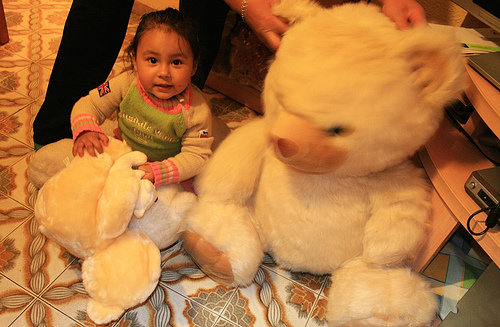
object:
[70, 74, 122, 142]
sleeve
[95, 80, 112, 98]
design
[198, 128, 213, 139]
design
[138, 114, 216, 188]
arm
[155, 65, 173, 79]
nose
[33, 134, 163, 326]
bear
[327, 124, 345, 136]
eye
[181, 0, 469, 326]
animal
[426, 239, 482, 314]
ground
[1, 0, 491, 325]
floor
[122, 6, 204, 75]
hair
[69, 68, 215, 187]
shirt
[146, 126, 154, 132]
writing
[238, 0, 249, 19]
bracelet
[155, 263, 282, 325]
tile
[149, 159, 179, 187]
stripes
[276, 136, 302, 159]
nose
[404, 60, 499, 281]
shelf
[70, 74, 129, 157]
arm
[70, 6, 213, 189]
child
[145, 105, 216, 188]
sleeve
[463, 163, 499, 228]
electronic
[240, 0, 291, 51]
hand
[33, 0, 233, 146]
pants